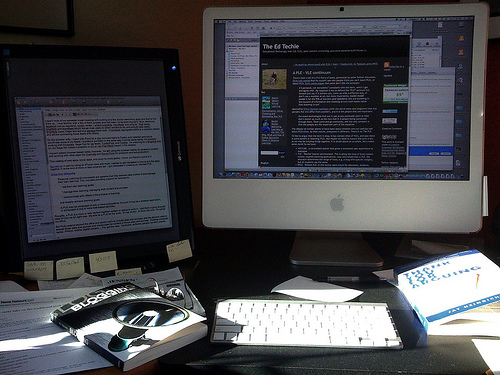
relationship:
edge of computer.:
[12, 235, 202, 278] [1, 43, 195, 275]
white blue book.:
[393, 247, 499, 338] [392, 247, 498, 337]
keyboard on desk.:
[208, 298, 403, 351] [157, 227, 498, 375]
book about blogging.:
[49, 281, 209, 372] [68, 284, 138, 313]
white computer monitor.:
[202, 3, 491, 233] [200, 2, 489, 232]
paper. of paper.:
[270, 274, 366, 302] [270, 273, 362, 302]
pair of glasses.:
[144, 261, 200, 311] [144, 258, 200, 311]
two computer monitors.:
[0, 0, 489, 274] [1, 1, 490, 272]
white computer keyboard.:
[210, 299, 404, 351] [208, 298, 403, 351]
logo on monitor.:
[329, 193, 345, 213] [200, 2, 489, 232]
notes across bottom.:
[22, 238, 194, 280] [21, 238, 196, 279]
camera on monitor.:
[338, 6, 346, 14] [200, 2, 489, 232]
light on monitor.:
[169, 65, 178, 72] [0, 43, 197, 272]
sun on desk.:
[0, 248, 500, 374] [157, 227, 498, 375]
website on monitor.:
[259, 29, 410, 166] [200, 2, 489, 232]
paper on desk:
[270, 273, 362, 302] [157, 227, 498, 375]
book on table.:
[392, 247, 498, 337] [157, 227, 498, 375]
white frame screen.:
[202, 3, 491, 233] [213, 14, 470, 180]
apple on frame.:
[329, 193, 345, 213] [202, 3, 490, 232]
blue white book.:
[391, 248, 499, 338] [392, 247, 498, 337]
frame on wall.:
[1, 0, 76, 38] [0, 0, 499, 227]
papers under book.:
[0, 267, 208, 375] [49, 281, 209, 372]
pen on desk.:
[309, 275, 381, 284] [157, 227, 498, 375]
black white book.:
[49, 281, 209, 370] [49, 281, 209, 372]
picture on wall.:
[0, 1, 74, 37] [0, 0, 499, 227]